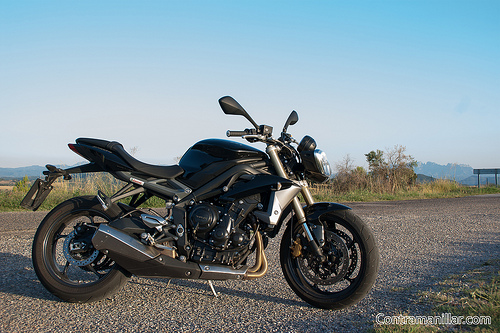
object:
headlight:
[314, 148, 333, 177]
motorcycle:
[17, 95, 378, 310]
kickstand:
[207, 279, 218, 297]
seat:
[75, 137, 183, 180]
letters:
[479, 315, 493, 326]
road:
[0, 195, 500, 333]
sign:
[472, 169, 500, 175]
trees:
[384, 144, 414, 195]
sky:
[0, 1, 499, 186]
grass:
[386, 266, 500, 333]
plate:
[20, 178, 54, 212]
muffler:
[82, 223, 270, 281]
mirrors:
[218, 95, 259, 127]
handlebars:
[226, 128, 250, 139]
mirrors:
[283, 110, 299, 132]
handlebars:
[286, 133, 292, 138]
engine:
[182, 197, 251, 265]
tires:
[280, 209, 379, 309]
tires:
[30, 195, 131, 303]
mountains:
[457, 175, 500, 188]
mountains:
[0, 159, 86, 185]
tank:
[179, 138, 268, 190]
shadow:
[0, 252, 310, 308]